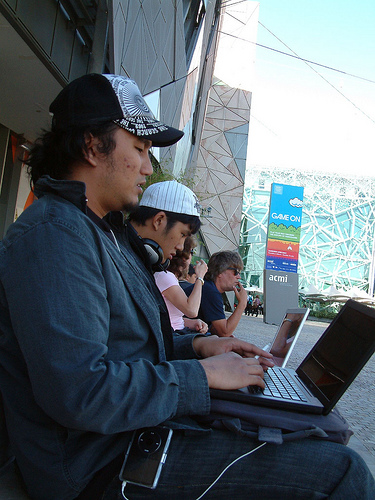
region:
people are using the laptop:
[68, 69, 358, 435]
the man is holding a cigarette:
[230, 334, 304, 390]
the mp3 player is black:
[115, 417, 189, 494]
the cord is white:
[206, 447, 246, 489]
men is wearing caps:
[53, 72, 183, 267]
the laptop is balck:
[172, 282, 367, 410]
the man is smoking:
[199, 242, 269, 336]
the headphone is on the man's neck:
[127, 210, 195, 283]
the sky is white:
[284, 137, 340, 167]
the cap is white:
[141, 176, 221, 251]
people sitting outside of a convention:
[16, 48, 368, 489]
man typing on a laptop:
[11, 71, 365, 424]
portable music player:
[87, 391, 183, 499]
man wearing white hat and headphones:
[114, 149, 209, 284]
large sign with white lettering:
[253, 170, 320, 350]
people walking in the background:
[239, 268, 266, 318]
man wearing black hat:
[37, 56, 188, 217]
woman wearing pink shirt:
[145, 205, 212, 334]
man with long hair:
[29, 47, 186, 231]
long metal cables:
[208, 2, 368, 139]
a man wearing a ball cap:
[6, 59, 182, 308]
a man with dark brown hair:
[13, 53, 181, 214]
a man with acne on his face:
[18, 86, 177, 242]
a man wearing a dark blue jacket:
[8, 69, 186, 479]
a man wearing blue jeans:
[40, 79, 373, 495]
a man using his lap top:
[0, 120, 367, 487]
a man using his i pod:
[37, 392, 228, 496]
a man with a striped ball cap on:
[113, 169, 223, 279]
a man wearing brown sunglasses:
[189, 236, 260, 344]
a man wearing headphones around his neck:
[121, 178, 219, 301]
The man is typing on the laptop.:
[200, 313, 359, 418]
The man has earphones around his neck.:
[131, 217, 187, 268]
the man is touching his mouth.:
[208, 251, 263, 321]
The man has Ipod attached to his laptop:
[111, 410, 193, 485]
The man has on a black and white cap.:
[60, 74, 210, 158]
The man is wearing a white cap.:
[144, 172, 210, 233]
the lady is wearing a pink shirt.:
[154, 260, 195, 333]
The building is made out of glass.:
[200, 77, 257, 252]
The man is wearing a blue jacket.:
[39, 199, 191, 437]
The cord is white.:
[214, 442, 272, 493]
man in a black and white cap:
[36, 73, 221, 416]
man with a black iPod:
[81, 320, 196, 497]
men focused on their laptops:
[55, 88, 346, 445]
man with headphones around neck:
[123, 136, 299, 382]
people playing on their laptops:
[70, 111, 373, 459]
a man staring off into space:
[192, 214, 316, 413]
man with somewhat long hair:
[24, 84, 294, 469]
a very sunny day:
[22, 54, 372, 490]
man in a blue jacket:
[33, 98, 235, 475]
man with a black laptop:
[139, 191, 374, 463]